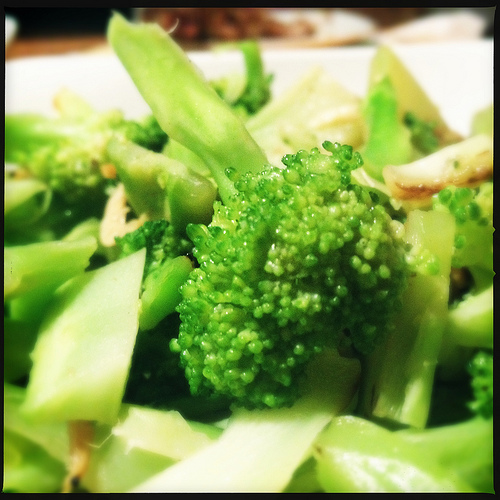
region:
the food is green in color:
[175, 145, 416, 416]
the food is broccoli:
[173, 145, 396, 403]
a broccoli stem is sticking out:
[107, 6, 295, 202]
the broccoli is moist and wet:
[179, 143, 410, 403]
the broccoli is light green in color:
[376, 209, 456, 426]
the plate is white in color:
[2, 43, 492, 495]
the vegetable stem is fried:
[385, 132, 499, 208]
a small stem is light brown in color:
[53, 419, 105, 493]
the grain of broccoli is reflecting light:
[240, 239, 250, 249]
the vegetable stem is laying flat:
[27, 253, 161, 424]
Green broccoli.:
[187, 205, 391, 437]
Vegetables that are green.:
[97, 292, 449, 483]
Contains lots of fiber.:
[80, 307, 442, 478]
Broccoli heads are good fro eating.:
[83, 133, 418, 408]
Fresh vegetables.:
[50, 227, 270, 421]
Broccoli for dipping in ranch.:
[278, 225, 433, 409]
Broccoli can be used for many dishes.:
[90, 212, 452, 423]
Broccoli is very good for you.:
[145, 225, 462, 405]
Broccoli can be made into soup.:
[180, 195, 320, 385]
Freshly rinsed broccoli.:
[256, 252, 421, 408]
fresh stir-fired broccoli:
[23, 20, 479, 471]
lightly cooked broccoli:
[28, 30, 475, 454]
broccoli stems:
[40, 207, 484, 498]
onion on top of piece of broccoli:
[370, 40, 496, 260]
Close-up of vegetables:
[7, 25, 497, 460]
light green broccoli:
[139, 115, 431, 420]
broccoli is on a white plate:
[15, 15, 497, 498]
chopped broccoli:
[45, 61, 493, 465]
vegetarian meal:
[12, 21, 479, 421]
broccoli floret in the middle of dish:
[135, 88, 445, 438]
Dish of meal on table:
[8, 31, 498, 488]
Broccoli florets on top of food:
[118, 31, 432, 418]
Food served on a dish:
[18, 11, 498, 498]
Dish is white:
[7, 26, 497, 146]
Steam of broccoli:
[0, 20, 200, 495]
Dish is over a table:
[0, 30, 295, 70]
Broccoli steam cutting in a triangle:
[30, 247, 145, 441]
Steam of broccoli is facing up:
[97, 12, 418, 424]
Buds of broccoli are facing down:
[180, 144, 402, 411]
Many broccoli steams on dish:
[8, 10, 498, 488]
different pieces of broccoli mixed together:
[70, 91, 466, 441]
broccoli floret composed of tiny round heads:
[170, 150, 395, 425]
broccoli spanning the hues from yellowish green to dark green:
[80, 100, 421, 355]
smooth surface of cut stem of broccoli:
[55, 240, 140, 415]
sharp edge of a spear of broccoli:
[100, 236, 145, 431]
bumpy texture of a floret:
[200, 165, 350, 396]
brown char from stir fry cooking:
[335, 151, 485, 201]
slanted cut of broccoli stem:
[96, 12, 267, 157]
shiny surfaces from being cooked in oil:
[165, 127, 385, 402]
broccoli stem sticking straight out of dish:
[80, 11, 292, 216]